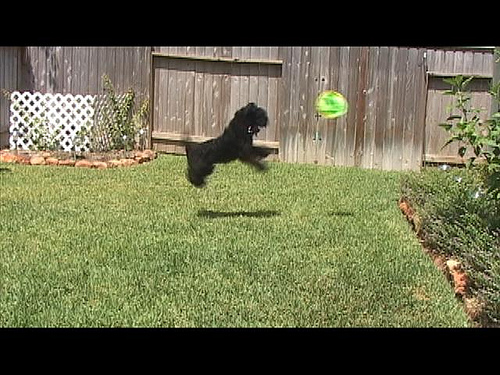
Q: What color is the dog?
A: Black.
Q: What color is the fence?
A: Brown.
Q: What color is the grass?
A: Green.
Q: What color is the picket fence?
A: White.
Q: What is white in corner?
A: Lattice fence.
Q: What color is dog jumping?
A: Black.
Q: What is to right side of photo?
A: Row of plants.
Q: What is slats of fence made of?
A: Wooden.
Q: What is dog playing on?
A: Thick lawn.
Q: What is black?
A: Dog.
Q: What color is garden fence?
A: White.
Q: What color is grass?
A: Green.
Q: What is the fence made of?
A: Wooden.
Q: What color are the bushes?
A: Green.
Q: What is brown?
A: Fence.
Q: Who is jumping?
A: Dog.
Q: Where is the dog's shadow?
A: On the grass.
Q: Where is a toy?
A: In the air.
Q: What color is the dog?
A: Black.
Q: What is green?
A: Grass.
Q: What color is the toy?
A: Yellow and green.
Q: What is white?
A: Small fence.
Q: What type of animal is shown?
A: A dog.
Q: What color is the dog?
A: Black.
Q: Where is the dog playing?
A: In a yard.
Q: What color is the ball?
A: Green and yellow.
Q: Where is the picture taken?
A: A back yard.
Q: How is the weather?
A: Sunny.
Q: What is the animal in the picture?
A: A dog.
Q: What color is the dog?
A: Black.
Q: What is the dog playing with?
A: A ball.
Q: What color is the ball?
A: Yellow and green.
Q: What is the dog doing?
A: Jumping in the air for the ball.